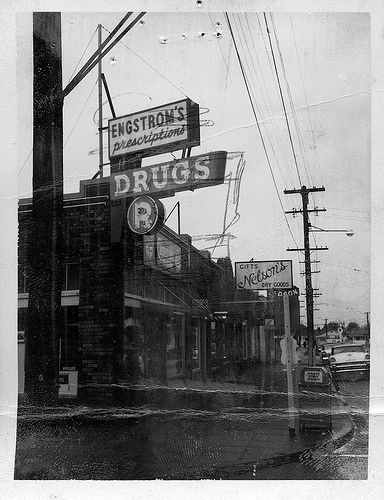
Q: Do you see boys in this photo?
A: No, there are no boys.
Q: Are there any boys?
A: No, there are no boys.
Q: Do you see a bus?
A: No, there are no buses.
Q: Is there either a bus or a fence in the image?
A: No, there are no buses or fences.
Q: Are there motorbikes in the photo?
A: No, there are no motorbikes.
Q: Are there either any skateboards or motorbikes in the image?
A: No, there are no motorbikes or skateboards.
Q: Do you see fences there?
A: No, there are no fences.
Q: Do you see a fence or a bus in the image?
A: No, there are no fences or buses.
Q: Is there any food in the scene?
A: No, there is no food.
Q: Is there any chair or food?
A: No, there are no food or chairs.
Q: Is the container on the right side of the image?
A: Yes, the container is on the right of the image.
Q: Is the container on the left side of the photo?
A: No, the container is on the right of the image.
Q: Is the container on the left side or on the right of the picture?
A: The container is on the right of the image.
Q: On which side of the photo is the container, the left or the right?
A: The container is on the right of the image.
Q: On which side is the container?
A: The container is on the right of the image.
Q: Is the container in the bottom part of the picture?
A: Yes, the container is in the bottom of the image.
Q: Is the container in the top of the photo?
A: No, the container is in the bottom of the image.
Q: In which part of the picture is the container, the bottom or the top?
A: The container is in the bottom of the image.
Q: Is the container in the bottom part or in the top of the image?
A: The container is in the bottom of the image.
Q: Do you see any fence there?
A: No, there are no fences.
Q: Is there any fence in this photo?
A: No, there are no fences.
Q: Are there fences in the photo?
A: No, there are no fences.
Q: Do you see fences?
A: No, there are no fences.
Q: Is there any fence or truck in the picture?
A: No, there are no fences or trucks.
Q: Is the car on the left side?
A: No, the car is on the right of the image.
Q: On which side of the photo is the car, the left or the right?
A: The car is on the right of the image.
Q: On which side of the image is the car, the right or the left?
A: The car is on the right of the image.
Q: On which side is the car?
A: The car is on the right of the image.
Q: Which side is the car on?
A: The car is on the right of the image.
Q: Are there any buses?
A: No, there are no buses.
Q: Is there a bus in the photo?
A: No, there are no buses.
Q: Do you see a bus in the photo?
A: No, there are no buses.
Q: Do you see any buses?
A: No, there are no buses.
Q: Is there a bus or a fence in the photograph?
A: No, there are no buses or fences.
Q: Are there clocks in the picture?
A: No, there are no clocks.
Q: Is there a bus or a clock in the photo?
A: No, there are no clocks or buses.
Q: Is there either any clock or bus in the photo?
A: No, there are no clocks or buses.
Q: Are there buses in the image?
A: No, there are no buses.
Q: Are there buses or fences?
A: No, there are no buses or fences.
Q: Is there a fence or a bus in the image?
A: No, there are no buses or fences.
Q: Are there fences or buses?
A: No, there are no buses or fences.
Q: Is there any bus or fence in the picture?
A: No, there are no buses or fences.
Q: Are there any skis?
A: No, there are no skis.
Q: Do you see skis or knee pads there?
A: No, there are no skis or knee pads.